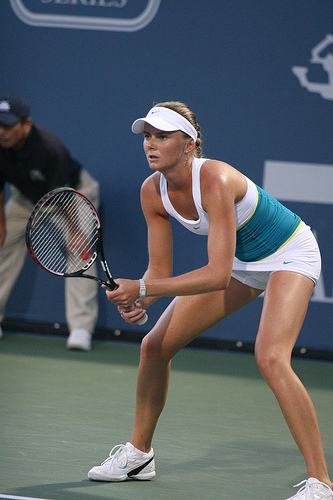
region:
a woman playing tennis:
[31, 94, 331, 483]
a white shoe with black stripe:
[83, 440, 174, 487]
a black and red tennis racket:
[25, 183, 153, 346]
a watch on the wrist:
[139, 272, 153, 309]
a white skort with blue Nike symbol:
[221, 242, 332, 302]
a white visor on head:
[121, 103, 213, 168]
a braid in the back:
[192, 112, 210, 171]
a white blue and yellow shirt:
[147, 168, 318, 280]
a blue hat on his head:
[3, 91, 38, 132]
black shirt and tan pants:
[5, 147, 116, 351]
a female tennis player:
[32, 100, 332, 498]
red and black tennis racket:
[25, 184, 146, 323]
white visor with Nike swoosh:
[132, 108, 196, 141]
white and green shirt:
[158, 155, 300, 262]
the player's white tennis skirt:
[230, 221, 318, 290]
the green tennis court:
[2, 334, 332, 499]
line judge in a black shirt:
[2, 96, 100, 347]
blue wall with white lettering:
[1, 0, 332, 357]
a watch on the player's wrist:
[137, 279, 144, 298]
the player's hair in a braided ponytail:
[152, 101, 202, 158]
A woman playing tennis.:
[25, 100, 332, 497]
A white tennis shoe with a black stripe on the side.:
[86, 441, 155, 481]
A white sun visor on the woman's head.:
[131, 106, 197, 141]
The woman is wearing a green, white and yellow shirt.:
[158, 157, 302, 260]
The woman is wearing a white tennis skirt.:
[230, 222, 318, 289]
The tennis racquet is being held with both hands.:
[25, 185, 147, 326]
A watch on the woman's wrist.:
[138, 277, 146, 299]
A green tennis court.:
[0, 333, 332, 499]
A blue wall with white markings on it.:
[0, 0, 332, 344]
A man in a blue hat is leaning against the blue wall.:
[0, 95, 99, 350]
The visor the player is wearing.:
[132, 112, 199, 143]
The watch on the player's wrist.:
[137, 281, 146, 298]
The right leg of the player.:
[261, 271, 324, 483]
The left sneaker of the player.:
[88, 445, 156, 484]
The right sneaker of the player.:
[283, 472, 331, 497]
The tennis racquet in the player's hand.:
[24, 194, 150, 335]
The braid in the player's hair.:
[191, 120, 206, 158]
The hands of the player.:
[103, 277, 144, 325]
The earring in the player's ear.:
[184, 146, 190, 157]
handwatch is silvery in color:
[134, 276, 155, 301]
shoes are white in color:
[89, 440, 159, 492]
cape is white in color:
[151, 105, 175, 131]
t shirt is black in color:
[5, 154, 81, 187]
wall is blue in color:
[209, 70, 263, 129]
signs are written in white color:
[292, 48, 331, 98]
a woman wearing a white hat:
[130, 91, 203, 150]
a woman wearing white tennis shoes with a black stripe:
[88, 437, 155, 482]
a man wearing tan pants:
[0, 187, 98, 336]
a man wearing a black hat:
[0, 94, 30, 126]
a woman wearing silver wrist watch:
[138, 275, 151, 299]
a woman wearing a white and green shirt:
[146, 173, 299, 251]